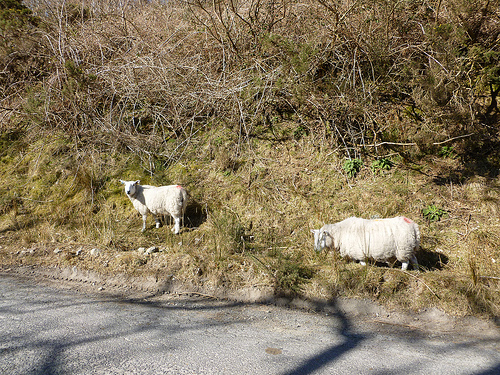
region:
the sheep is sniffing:
[257, 172, 394, 303]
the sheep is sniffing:
[303, 170, 398, 325]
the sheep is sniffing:
[303, 187, 413, 355]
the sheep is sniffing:
[271, 172, 436, 354]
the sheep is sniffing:
[338, 163, 406, 303]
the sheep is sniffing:
[298, 185, 348, 272]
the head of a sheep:
[116, 170, 143, 199]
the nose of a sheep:
[122, 187, 132, 197]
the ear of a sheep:
[131, 175, 143, 187]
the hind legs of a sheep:
[166, 213, 187, 238]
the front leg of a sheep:
[138, 207, 151, 235]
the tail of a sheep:
[411, 222, 426, 250]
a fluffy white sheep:
[308, 209, 430, 274]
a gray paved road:
[1, 272, 499, 374]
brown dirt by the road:
[3, 255, 499, 340]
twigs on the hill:
[1, 0, 498, 172]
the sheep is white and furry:
[98, 127, 424, 320]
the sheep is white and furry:
[281, 203, 498, 336]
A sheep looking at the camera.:
[119, 178, 189, 237]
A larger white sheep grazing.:
[307, 211, 422, 276]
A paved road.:
[3, 263, 498, 373]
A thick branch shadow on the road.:
[278, 324, 366, 374]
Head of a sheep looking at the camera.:
[115, 176, 142, 199]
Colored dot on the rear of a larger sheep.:
[403, 217, 412, 227]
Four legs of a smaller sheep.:
[136, 208, 187, 235]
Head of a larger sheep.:
[305, 226, 333, 256]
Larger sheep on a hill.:
[304, 214, 421, 275]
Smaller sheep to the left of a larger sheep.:
[117, 179, 187, 231]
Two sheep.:
[108, 167, 430, 277]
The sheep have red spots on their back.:
[385, 206, 425, 234]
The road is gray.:
[4, 281, 346, 373]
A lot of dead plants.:
[47, 3, 424, 131]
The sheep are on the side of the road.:
[99, 163, 456, 298]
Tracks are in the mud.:
[26, 255, 268, 327]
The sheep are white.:
[96, 161, 438, 283]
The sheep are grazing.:
[64, 163, 484, 296]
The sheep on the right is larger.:
[309, 196, 440, 278]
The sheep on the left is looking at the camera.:
[97, 166, 217, 238]